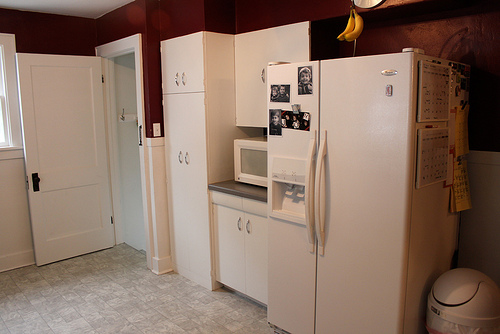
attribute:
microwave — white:
[228, 133, 273, 194]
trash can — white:
[422, 261, 495, 332]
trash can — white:
[417, 256, 493, 332]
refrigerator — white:
[257, 47, 482, 332]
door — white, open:
[8, 45, 122, 274]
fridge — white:
[231, 36, 438, 307]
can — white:
[404, 260, 484, 331]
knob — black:
[18, 158, 55, 203]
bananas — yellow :
[326, 20, 376, 61]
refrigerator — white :
[253, 51, 444, 320]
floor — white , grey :
[29, 234, 274, 319]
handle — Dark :
[18, 126, 48, 170]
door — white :
[13, 49, 168, 294]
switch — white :
[134, 103, 178, 160]